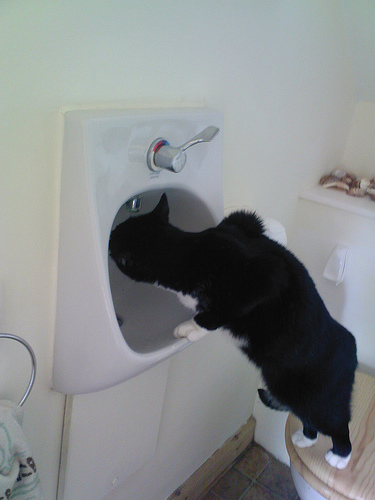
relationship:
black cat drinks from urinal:
[109, 191, 358, 470] [51, 108, 226, 394]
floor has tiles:
[171, 430, 316, 498] [207, 441, 297, 500]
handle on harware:
[145, 122, 217, 175] [144, 134, 180, 173]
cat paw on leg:
[291, 431, 312, 451] [174, 286, 270, 340]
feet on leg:
[321, 446, 351, 471] [318, 372, 351, 468]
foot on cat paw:
[170, 317, 197, 335] [291, 431, 312, 451]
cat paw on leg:
[291, 431, 312, 451] [293, 418, 318, 449]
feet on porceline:
[321, 446, 351, 471] [50, 109, 223, 396]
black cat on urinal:
[109, 191, 358, 470] [51, 108, 226, 394]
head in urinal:
[110, 189, 170, 283] [51, 108, 226, 394]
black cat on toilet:
[109, 191, 358, 470] [284, 371, 372, 497]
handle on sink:
[145, 122, 217, 175] [49, 100, 233, 399]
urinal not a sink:
[51, 108, 226, 394] [49, 100, 233, 399]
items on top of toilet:
[319, 167, 374, 199] [285, 168, 373, 498]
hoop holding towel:
[0, 323, 92, 482] [4, 406, 51, 438]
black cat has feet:
[109, 191, 358, 470] [321, 446, 351, 471]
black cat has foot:
[109, 191, 358, 470] [290, 426, 318, 449]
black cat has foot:
[109, 191, 358, 470] [174, 320, 197, 337]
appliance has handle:
[50, 110, 244, 388] [146, 114, 215, 170]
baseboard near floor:
[166, 416, 257, 498] [202, 439, 302, 499]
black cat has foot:
[109, 191, 358, 470] [171, 318, 205, 343]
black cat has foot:
[109, 191, 358, 470] [322, 445, 354, 470]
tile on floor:
[230, 431, 276, 493] [200, 424, 323, 493]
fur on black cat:
[210, 258, 267, 293] [109, 191, 358, 470]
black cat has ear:
[109, 191, 358, 470] [135, 175, 195, 228]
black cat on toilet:
[109, 191, 358, 470] [284, 239, 363, 496]